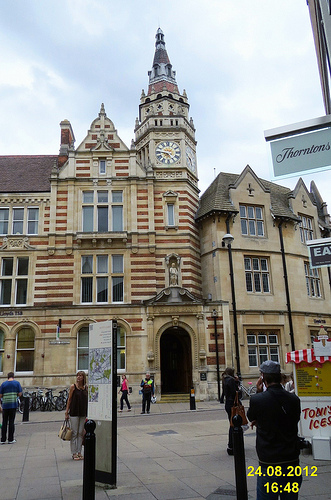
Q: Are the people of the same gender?
A: No, they are both male and female.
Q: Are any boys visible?
A: No, there are no boys.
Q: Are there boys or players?
A: No, there are no boys or players.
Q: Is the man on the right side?
A: Yes, the man is on the right of the image.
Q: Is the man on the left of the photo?
A: No, the man is on the right of the image.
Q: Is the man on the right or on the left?
A: The man is on the right of the image.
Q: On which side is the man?
A: The man is on the right of the image.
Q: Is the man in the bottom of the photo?
A: Yes, the man is in the bottom of the image.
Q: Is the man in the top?
A: No, the man is in the bottom of the image.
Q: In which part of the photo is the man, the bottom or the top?
A: The man is in the bottom of the image.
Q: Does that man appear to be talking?
A: Yes, the man is talking.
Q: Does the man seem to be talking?
A: Yes, the man is talking.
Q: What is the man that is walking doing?
A: The man is talking.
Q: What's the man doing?
A: The man is talking.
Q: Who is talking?
A: The man is talking.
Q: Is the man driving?
A: No, the man is talking.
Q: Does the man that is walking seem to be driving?
A: No, the man is talking.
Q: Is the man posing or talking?
A: The man is talking.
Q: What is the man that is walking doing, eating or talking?
A: The man is talking.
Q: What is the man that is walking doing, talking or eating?
A: The man is talking.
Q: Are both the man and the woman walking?
A: Yes, both the man and the woman are walking.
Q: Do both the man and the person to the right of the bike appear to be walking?
A: Yes, both the man and the woman are walking.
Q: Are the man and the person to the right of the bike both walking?
A: Yes, both the man and the woman are walking.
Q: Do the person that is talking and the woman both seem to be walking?
A: Yes, both the man and the woman are walking.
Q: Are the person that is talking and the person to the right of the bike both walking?
A: Yes, both the man and the woman are walking.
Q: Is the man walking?
A: Yes, the man is walking.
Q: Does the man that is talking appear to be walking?
A: Yes, the man is walking.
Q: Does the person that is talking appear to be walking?
A: Yes, the man is walking.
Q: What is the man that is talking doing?
A: The man is walking.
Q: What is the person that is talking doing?
A: The man is walking.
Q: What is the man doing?
A: The man is walking.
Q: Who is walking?
A: The man is walking.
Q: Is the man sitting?
A: No, the man is walking.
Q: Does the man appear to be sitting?
A: No, the man is walking.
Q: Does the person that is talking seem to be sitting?
A: No, the man is walking.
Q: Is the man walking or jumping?
A: The man is walking.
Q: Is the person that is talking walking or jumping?
A: The man is walking.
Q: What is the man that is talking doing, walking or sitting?
A: The man is walking.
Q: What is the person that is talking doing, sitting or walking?
A: The man is walking.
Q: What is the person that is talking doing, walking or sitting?
A: The man is walking.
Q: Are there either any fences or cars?
A: No, there are no cars or fences.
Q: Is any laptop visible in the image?
A: No, there are no laptops.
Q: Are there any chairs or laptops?
A: No, there are no laptops or chairs.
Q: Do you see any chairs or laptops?
A: No, there are no laptops or chairs.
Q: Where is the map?
A: The map is on the sidewalk.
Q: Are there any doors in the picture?
A: Yes, there is a door.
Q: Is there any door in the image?
A: Yes, there is a door.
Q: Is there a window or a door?
A: Yes, there is a door.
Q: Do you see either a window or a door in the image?
A: Yes, there is a door.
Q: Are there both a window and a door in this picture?
A: Yes, there are both a door and a window.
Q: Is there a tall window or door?
A: Yes, there is a tall door.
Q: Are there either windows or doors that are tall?
A: Yes, the door is tall.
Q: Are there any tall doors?
A: Yes, there is a tall door.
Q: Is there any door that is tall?
A: Yes, there is a door that is tall.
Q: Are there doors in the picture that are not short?
A: Yes, there is a tall door.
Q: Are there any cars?
A: No, there are no cars.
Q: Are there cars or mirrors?
A: No, there are no cars or mirrors.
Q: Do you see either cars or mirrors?
A: No, there are no cars or mirrors.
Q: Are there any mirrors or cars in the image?
A: No, there are no cars or mirrors.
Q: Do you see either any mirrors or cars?
A: No, there are no cars or mirrors.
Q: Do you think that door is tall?
A: Yes, the door is tall.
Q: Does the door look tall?
A: Yes, the door is tall.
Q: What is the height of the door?
A: The door is tall.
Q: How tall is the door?
A: The door is tall.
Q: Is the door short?
A: No, the door is tall.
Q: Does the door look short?
A: No, the door is tall.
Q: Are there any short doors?
A: No, there is a door but it is tall.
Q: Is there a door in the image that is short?
A: No, there is a door but it is tall.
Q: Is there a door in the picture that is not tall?
A: No, there is a door but it is tall.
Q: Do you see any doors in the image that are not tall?
A: No, there is a door but it is tall.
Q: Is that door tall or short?
A: The door is tall.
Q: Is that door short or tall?
A: The door is tall.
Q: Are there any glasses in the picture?
A: No, there are no glasses.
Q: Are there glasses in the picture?
A: No, there are no glasses.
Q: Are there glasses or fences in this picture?
A: No, there are no glasses or fences.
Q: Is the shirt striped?
A: Yes, the shirt is striped.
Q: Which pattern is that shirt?
A: The shirt is striped.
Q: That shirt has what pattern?
A: The shirt is striped.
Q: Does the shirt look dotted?
A: No, the shirt is striped.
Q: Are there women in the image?
A: Yes, there is a woman.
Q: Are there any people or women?
A: Yes, there is a woman.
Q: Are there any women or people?
A: Yes, there is a woman.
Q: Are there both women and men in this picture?
A: Yes, there are both a woman and a man.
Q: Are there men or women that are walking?
A: Yes, the woman is walking.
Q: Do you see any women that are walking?
A: Yes, there is a woman that is walking.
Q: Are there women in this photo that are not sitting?
A: Yes, there is a woman that is walking.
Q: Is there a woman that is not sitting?
A: Yes, there is a woman that is walking.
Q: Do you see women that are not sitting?
A: Yes, there is a woman that is walking .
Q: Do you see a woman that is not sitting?
A: Yes, there is a woman that is walking .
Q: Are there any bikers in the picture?
A: No, there are no bikers.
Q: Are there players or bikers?
A: No, there are no bikers or players.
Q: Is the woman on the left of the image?
A: Yes, the woman is on the left of the image.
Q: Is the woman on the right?
A: No, the woman is on the left of the image.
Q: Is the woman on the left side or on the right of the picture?
A: The woman is on the left of the image.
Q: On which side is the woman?
A: The woman is on the left of the image.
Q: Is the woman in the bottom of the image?
A: Yes, the woman is in the bottom of the image.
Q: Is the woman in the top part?
A: No, the woman is in the bottom of the image.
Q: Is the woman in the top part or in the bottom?
A: The woman is in the bottom of the image.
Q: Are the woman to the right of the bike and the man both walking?
A: Yes, both the woman and the man are walking.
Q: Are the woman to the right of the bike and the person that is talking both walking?
A: Yes, both the woman and the man are walking.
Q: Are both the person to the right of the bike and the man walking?
A: Yes, both the woman and the man are walking.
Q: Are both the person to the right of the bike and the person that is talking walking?
A: Yes, both the woman and the man are walking.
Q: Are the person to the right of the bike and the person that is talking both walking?
A: Yes, both the woman and the man are walking.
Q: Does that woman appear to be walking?
A: Yes, the woman is walking.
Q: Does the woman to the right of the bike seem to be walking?
A: Yes, the woman is walking.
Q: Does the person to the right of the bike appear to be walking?
A: Yes, the woman is walking.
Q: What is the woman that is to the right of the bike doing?
A: The woman is walking.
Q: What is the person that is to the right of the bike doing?
A: The woman is walking.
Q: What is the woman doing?
A: The woman is walking.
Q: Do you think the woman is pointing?
A: No, the woman is walking.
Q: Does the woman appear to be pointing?
A: No, the woman is walking.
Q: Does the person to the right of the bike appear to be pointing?
A: No, the woman is walking.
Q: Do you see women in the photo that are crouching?
A: No, there is a woman but she is walking.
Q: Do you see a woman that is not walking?
A: No, there is a woman but she is walking.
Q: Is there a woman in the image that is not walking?
A: No, there is a woman but she is walking.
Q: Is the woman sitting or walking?
A: The woman is walking.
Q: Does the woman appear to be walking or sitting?
A: The woman is walking.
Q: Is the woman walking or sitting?
A: The woman is walking.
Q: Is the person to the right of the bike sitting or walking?
A: The woman is walking.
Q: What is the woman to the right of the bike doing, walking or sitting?
A: The woman is walking.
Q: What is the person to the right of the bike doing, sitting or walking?
A: The woman is walking.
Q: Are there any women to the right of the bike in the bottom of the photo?
A: Yes, there is a woman to the right of the bike.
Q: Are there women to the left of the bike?
A: No, the woman is to the right of the bike.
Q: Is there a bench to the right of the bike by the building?
A: No, there is a woman to the right of the bike.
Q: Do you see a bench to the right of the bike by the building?
A: No, there is a woman to the right of the bike.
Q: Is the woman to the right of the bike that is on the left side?
A: Yes, the woman is to the right of the bike.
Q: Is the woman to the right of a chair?
A: No, the woman is to the right of the bike.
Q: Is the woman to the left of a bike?
A: No, the woman is to the right of a bike.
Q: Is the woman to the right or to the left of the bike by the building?
A: The woman is to the right of the bike.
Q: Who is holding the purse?
A: The woman is holding the purse.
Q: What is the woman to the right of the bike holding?
A: The woman is holding the purse.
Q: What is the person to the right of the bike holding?
A: The woman is holding the purse.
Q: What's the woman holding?
A: The woman is holding the purse.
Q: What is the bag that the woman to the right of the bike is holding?
A: The bag is a purse.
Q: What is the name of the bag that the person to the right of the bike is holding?
A: The bag is a purse.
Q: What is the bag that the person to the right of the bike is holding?
A: The bag is a purse.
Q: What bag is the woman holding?
A: The woman is holding the purse.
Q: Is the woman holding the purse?
A: Yes, the woman is holding the purse.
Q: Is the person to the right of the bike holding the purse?
A: Yes, the woman is holding the purse.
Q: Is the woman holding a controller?
A: No, the woman is holding the purse.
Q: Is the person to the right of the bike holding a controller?
A: No, the woman is holding the purse.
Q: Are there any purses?
A: Yes, there is a purse.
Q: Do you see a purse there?
A: Yes, there is a purse.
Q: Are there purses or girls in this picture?
A: Yes, there is a purse.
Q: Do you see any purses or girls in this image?
A: Yes, there is a purse.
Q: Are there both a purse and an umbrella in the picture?
A: No, there is a purse but no umbrellas.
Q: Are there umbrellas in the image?
A: No, there are no umbrellas.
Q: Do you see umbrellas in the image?
A: No, there are no umbrellas.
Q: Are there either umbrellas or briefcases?
A: No, there are no umbrellas or briefcases.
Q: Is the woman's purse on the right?
A: No, the purse is on the left of the image.